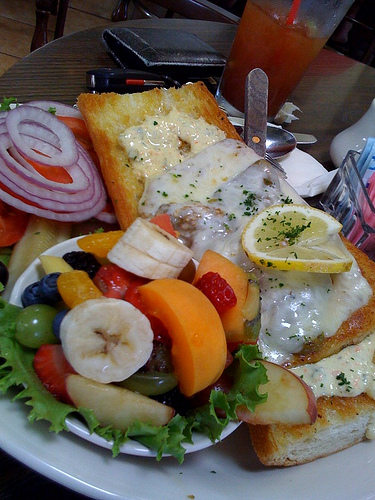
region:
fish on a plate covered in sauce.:
[73, 81, 373, 468]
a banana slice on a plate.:
[39, 289, 161, 410]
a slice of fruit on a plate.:
[123, 266, 231, 393]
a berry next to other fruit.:
[185, 266, 243, 316]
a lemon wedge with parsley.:
[234, 201, 349, 287]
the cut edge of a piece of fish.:
[241, 417, 370, 470]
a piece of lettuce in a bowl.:
[0, 257, 270, 469]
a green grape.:
[11, 286, 68, 356]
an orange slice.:
[50, 261, 109, 318]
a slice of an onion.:
[0, 97, 113, 229]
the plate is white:
[177, 479, 188, 496]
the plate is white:
[193, 480, 210, 497]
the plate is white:
[199, 471, 212, 498]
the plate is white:
[205, 486, 215, 496]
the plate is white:
[223, 484, 236, 497]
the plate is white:
[214, 491, 223, 498]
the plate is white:
[207, 473, 219, 498]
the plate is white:
[208, 484, 221, 499]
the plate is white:
[210, 495, 214, 499]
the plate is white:
[201, 482, 211, 496]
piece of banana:
[60, 297, 143, 373]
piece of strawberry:
[44, 353, 72, 406]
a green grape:
[22, 293, 61, 357]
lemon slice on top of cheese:
[257, 207, 345, 286]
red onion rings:
[6, 105, 99, 225]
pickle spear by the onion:
[9, 210, 84, 310]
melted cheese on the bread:
[195, 180, 346, 337]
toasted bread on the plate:
[60, 75, 230, 168]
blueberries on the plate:
[17, 274, 63, 304]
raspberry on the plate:
[190, 268, 241, 313]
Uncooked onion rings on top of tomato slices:
[1, 89, 103, 237]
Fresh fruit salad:
[24, 224, 245, 420]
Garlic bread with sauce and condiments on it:
[75, 81, 294, 216]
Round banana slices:
[79, 208, 196, 384]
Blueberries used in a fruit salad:
[5, 274, 56, 306]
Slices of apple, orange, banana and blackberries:
[31, 237, 151, 316]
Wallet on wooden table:
[48, 5, 218, 84]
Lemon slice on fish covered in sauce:
[190, 150, 357, 291]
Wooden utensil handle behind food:
[218, 52, 293, 241]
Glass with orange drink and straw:
[213, 0, 351, 121]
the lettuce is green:
[204, 409, 215, 441]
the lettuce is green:
[192, 390, 215, 433]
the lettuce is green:
[200, 406, 213, 431]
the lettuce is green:
[199, 400, 210, 418]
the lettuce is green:
[205, 413, 217, 426]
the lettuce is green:
[210, 421, 220, 438]